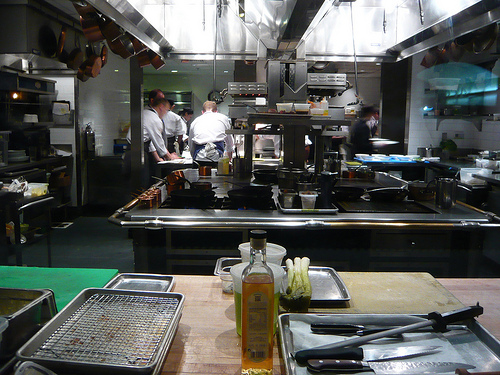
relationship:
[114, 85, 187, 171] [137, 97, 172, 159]
man wears person/white shirt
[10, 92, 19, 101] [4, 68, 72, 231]
light on stove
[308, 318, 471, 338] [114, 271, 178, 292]
knife laying on metal tray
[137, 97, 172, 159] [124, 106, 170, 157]
person/white shirt wearing shirt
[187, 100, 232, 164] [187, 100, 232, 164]
person/white shirt wearing person/white shirt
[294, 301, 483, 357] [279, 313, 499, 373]
knife sharpener laying on tray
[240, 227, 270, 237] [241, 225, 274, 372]
black cap on bottle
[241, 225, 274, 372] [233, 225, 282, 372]
bottle contains oil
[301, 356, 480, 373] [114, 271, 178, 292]
knife on metal tray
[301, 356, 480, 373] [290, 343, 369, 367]
knife has handle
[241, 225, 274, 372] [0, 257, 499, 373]
bottle on counter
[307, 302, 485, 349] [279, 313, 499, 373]
thermometer on tray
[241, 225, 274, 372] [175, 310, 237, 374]
bottle on table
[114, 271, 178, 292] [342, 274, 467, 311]
metal tray on table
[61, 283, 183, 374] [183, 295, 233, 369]
metal tray on table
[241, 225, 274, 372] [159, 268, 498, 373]
bottle on wooden surface